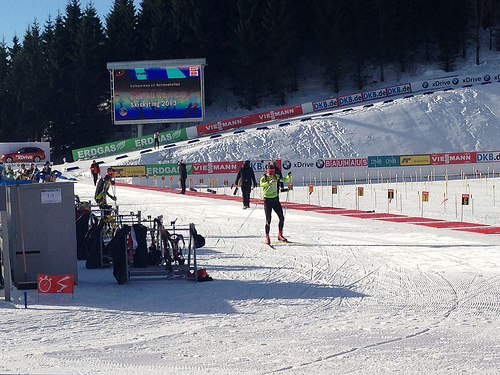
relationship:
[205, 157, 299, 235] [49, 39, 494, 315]
skiers on course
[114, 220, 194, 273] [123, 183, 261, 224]
racks on sidelines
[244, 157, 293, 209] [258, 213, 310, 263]
person on skis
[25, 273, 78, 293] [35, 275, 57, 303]
image of clock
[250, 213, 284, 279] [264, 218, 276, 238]
ski on foot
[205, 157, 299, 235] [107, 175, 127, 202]
skiers on crutch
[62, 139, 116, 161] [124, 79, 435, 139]
banner on hill